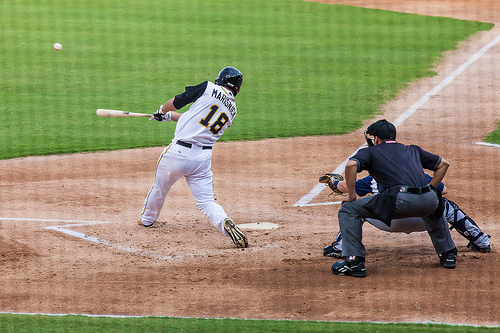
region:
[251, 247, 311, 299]
part of a brown ground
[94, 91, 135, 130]
part of a baseball club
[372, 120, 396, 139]
part of a cap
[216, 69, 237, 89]
part of a helmet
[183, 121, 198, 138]
part of a white top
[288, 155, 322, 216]
part of a white line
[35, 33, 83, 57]
part of a baseball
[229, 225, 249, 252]
sole of a shoe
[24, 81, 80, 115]
part of a green ground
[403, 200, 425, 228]
part of a trouser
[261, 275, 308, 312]
part of the ground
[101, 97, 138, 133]
part of the club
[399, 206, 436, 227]
part of a trouser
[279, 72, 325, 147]
part of green ground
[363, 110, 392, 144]
part of a black cap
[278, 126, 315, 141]
edge of the grass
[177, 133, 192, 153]
part of a belt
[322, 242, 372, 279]
part of a shoe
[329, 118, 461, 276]
umpire squatting behind catcher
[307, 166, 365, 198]
catcher's mitt ready to catch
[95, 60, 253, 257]
player swinging a bat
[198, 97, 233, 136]
shirt with number 18 on it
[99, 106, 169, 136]
wooden baseball bat mid-swing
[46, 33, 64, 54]
ball heading towards batter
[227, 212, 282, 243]
white plate on base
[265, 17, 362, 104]
green grass on baseball field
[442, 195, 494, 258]
shin guard on catcher's leg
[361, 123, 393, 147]
catcher wearing face mask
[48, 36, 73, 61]
this is a baseball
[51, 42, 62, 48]
the baseball is white in color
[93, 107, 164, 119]
this is a baseball bat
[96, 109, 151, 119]
the bat is made of wood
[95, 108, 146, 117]
the bat is wooden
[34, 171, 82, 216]
this is the ground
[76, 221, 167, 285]
the ground is sandy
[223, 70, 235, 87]
this is a helmet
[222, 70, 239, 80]
the helmet is black in color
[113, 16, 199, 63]
the carpet is green in color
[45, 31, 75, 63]
this is a ball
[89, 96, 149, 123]
this is a cricket bat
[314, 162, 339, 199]
this is a glove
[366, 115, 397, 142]
this is a cap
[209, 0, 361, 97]
this is the grass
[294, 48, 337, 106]
the grass is green in color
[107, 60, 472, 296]
these are players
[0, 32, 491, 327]
this is a cricket pitch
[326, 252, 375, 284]
this is a sport shoe of the man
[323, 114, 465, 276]
the man is squatting